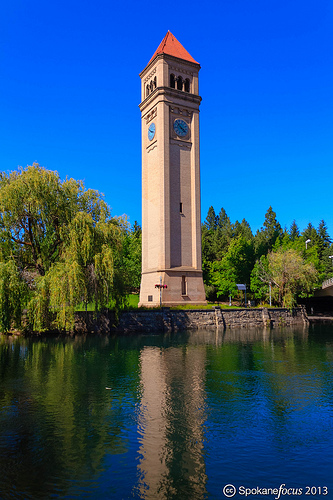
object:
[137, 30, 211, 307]
tower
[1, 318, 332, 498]
water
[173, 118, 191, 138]
clock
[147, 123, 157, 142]
clock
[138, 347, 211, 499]
reflection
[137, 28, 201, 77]
roof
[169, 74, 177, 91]
windows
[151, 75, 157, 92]
windows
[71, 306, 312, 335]
wall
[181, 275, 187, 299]
door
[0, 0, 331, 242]
sky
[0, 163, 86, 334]
trees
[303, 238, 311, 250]
pole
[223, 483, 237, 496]
cc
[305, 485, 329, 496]
year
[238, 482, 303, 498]
name